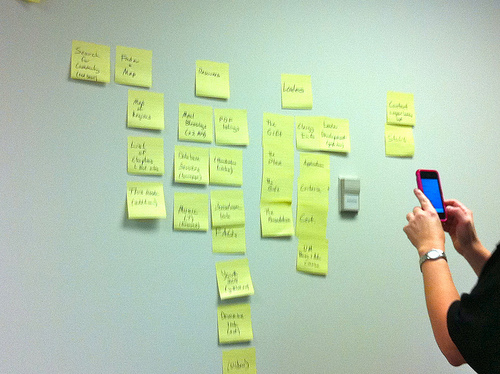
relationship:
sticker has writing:
[69, 30, 112, 81] [84, 63, 99, 74]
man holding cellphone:
[398, 204, 500, 340] [418, 163, 452, 218]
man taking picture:
[398, 204, 500, 340] [418, 180, 446, 202]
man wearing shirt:
[398, 204, 500, 340] [456, 286, 498, 355]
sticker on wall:
[69, 30, 112, 81] [25, 115, 69, 182]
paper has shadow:
[128, 174, 159, 217] [124, 218, 156, 236]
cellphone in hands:
[418, 163, 452, 218] [413, 224, 481, 251]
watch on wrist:
[420, 241, 445, 265] [456, 237, 489, 263]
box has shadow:
[331, 164, 365, 225] [344, 209, 358, 222]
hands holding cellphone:
[413, 224, 481, 251] [418, 163, 452, 218]